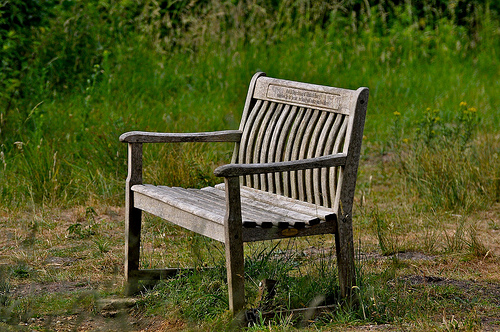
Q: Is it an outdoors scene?
A: Yes, it is outdoors.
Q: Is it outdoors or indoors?
A: It is outdoors.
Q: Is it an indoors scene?
A: No, it is outdoors.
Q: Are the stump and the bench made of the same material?
A: Yes, both the stump and the bench are made of wood.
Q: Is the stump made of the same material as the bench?
A: Yes, both the stump and the bench are made of wood.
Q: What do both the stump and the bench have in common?
A: The material, both the stump and the bench are wooden.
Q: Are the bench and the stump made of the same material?
A: Yes, both the bench and the stump are made of wood.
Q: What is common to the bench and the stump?
A: The material, both the bench and the stump are wooden.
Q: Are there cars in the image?
A: No, there are no cars.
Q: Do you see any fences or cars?
A: No, there are no cars or fences.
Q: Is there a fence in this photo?
A: No, there are no fences.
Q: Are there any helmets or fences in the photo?
A: No, there are no fences or helmets.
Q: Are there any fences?
A: No, there are no fences.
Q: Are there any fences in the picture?
A: No, there are no fences.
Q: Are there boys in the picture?
A: No, there are no boys.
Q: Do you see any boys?
A: No, there are no boys.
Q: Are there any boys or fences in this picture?
A: No, there are no boys or fences.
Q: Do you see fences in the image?
A: No, there are no fences.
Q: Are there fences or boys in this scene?
A: No, there are no fences or boys.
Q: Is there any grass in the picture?
A: Yes, there is grass.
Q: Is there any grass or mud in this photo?
A: Yes, there is grass.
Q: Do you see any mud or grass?
A: Yes, there is grass.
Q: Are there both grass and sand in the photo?
A: No, there is grass but no sand.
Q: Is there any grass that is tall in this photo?
A: Yes, there is tall grass.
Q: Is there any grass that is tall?
A: Yes, there is grass that is tall.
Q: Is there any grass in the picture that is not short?
A: Yes, there is tall grass.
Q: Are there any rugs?
A: No, there are no rugs.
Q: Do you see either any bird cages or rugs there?
A: No, there are no rugs or bird cages.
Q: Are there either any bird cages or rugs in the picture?
A: No, there are no rugs or bird cages.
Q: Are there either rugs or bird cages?
A: No, there are no rugs or bird cages.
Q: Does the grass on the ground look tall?
A: Yes, the grass is tall.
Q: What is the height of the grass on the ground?
A: The grass is tall.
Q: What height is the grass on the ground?
A: The grass is tall.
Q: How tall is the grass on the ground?
A: The grass is tall.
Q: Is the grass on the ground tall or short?
A: The grass is tall.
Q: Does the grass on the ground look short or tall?
A: The grass is tall.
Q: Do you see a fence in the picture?
A: No, there are no fences.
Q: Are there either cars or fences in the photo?
A: No, there are no fences or cars.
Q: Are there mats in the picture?
A: No, there are no mats.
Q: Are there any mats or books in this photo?
A: No, there are no mats or books.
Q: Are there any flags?
A: No, there are no flags.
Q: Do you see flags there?
A: No, there are no flags.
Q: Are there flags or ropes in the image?
A: No, there are no flags or ropes.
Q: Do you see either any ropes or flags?
A: No, there are no flags or ropes.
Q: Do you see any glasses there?
A: No, there are no glasses.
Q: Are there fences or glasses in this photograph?
A: No, there are no glasses or fences.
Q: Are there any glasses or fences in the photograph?
A: No, there are no glasses or fences.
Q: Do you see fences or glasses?
A: No, there are no glasses or fences.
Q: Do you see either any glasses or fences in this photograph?
A: No, there are no glasses or fences.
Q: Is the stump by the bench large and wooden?
A: Yes, the stump is large and wooden.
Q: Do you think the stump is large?
A: Yes, the stump is large.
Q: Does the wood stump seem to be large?
A: Yes, the stump is large.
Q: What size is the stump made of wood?
A: The stump is large.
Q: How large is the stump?
A: The stump is large.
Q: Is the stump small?
A: No, the stump is large.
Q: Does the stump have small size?
A: No, the stump is large.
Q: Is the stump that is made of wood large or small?
A: The stump is large.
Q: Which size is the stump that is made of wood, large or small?
A: The stump is large.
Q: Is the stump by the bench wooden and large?
A: Yes, the stump is wooden and large.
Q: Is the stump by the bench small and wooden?
A: No, the stump is wooden but large.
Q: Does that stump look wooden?
A: Yes, the stump is wooden.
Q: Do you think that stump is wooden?
A: Yes, the stump is wooden.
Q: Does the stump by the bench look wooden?
A: Yes, the stump is wooden.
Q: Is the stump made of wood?
A: Yes, the stump is made of wood.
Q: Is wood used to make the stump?
A: Yes, the stump is made of wood.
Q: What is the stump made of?
A: The stump is made of wood.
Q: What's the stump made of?
A: The stump is made of wood.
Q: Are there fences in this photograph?
A: No, there are no fences.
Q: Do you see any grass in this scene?
A: Yes, there is grass.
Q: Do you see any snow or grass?
A: Yes, there is grass.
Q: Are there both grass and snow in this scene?
A: No, there is grass but no snow.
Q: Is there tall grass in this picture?
A: Yes, there is tall grass.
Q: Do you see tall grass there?
A: Yes, there is tall grass.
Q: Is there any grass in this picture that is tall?
A: Yes, there is grass that is tall.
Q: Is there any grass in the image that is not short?
A: Yes, there is tall grass.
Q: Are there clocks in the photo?
A: No, there are no clocks.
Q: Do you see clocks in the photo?
A: No, there are no clocks.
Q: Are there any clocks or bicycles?
A: No, there are no clocks or bicycles.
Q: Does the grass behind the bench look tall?
A: Yes, the grass is tall.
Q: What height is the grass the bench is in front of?
A: The grass is tall.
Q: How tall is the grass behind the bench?
A: The grass is tall.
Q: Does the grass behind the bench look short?
A: No, the grass is tall.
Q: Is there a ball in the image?
A: No, there are no balls.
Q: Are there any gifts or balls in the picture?
A: No, there are no balls or gifts.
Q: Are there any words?
A: Yes, there are words.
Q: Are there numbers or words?
A: Yes, there are words.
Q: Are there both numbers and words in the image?
A: No, there are words but no numbers.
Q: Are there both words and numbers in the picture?
A: No, there are words but no numbers.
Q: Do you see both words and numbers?
A: No, there are words but no numbers.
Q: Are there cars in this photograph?
A: No, there are no cars.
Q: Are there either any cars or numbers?
A: No, there are no cars or numbers.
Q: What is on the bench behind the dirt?
A: The words are on the bench.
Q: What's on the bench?
A: The words are on the bench.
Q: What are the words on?
A: The words are on the bench.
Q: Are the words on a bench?
A: Yes, the words are on a bench.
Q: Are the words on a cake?
A: No, the words are on a bench.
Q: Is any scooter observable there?
A: No, there are no scooters.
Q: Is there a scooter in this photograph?
A: No, there are no scooters.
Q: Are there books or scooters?
A: No, there are no scooters or books.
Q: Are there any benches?
A: Yes, there is a bench.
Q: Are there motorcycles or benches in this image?
A: Yes, there is a bench.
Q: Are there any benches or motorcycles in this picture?
A: Yes, there is a bench.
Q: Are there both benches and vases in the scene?
A: No, there is a bench but no vases.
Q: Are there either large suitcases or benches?
A: Yes, there is a large bench.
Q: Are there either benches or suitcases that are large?
A: Yes, the bench is large.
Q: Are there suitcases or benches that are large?
A: Yes, the bench is large.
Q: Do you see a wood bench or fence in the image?
A: Yes, there is a wood bench.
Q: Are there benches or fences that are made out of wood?
A: Yes, the bench is made of wood.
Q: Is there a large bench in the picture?
A: Yes, there is a large bench.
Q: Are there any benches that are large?
A: Yes, there is a bench that is large.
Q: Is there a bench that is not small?
A: Yes, there is a large bench.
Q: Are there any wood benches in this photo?
A: Yes, there is a wood bench.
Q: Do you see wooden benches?
A: Yes, there is a wood bench.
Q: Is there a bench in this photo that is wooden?
A: Yes, there is a bench that is wooden.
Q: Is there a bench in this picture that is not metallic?
A: Yes, there is a wooden bench.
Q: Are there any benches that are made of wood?
A: Yes, there is a bench that is made of wood.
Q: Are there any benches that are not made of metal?
A: Yes, there is a bench that is made of wood.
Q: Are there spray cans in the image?
A: No, there are no spray cans.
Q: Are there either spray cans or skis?
A: No, there are no spray cans or skis.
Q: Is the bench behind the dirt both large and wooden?
A: Yes, the bench is large and wooden.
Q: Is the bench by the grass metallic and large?
A: No, the bench is large but wooden.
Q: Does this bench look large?
A: Yes, the bench is large.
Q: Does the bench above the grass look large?
A: Yes, the bench is large.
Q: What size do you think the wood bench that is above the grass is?
A: The bench is large.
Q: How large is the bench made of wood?
A: The bench is large.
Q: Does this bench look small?
A: No, the bench is large.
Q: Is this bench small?
A: No, the bench is large.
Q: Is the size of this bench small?
A: No, the bench is large.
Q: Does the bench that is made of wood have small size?
A: No, the bench is large.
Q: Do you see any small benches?
A: No, there is a bench but it is large.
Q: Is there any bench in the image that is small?
A: No, there is a bench but it is large.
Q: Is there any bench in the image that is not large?
A: No, there is a bench but it is large.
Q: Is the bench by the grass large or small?
A: The bench is large.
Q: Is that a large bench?
A: Yes, that is a large bench.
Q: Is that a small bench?
A: No, that is a large bench.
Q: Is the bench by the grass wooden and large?
A: Yes, the bench is wooden and large.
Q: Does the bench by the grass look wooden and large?
A: Yes, the bench is wooden and large.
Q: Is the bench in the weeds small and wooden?
A: No, the bench is wooden but large.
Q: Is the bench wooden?
A: Yes, the bench is wooden.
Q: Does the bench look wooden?
A: Yes, the bench is wooden.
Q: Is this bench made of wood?
A: Yes, the bench is made of wood.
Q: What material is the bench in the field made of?
A: The bench is made of wood.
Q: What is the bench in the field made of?
A: The bench is made of wood.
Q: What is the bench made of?
A: The bench is made of wood.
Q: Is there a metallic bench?
A: No, there is a bench but it is wooden.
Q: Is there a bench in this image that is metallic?
A: No, there is a bench but it is wooden.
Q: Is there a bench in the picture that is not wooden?
A: No, there is a bench but it is wooden.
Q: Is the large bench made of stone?
A: No, the bench is made of wood.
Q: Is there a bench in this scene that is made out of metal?
A: No, there is a bench but it is made of wood.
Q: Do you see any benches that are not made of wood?
A: No, there is a bench but it is made of wood.